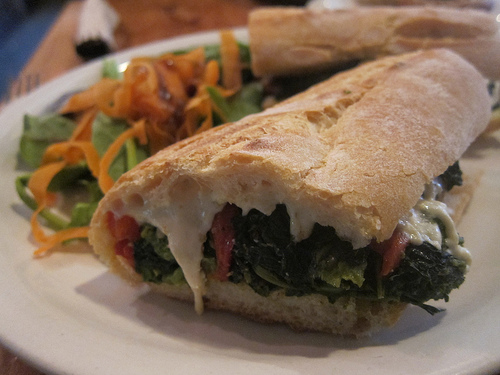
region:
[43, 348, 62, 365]
edge of a plate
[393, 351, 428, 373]
side of a plate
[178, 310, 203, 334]
inside of a plate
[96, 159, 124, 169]
section of vegetables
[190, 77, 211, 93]
part of orange vegetable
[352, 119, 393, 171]
section of a bread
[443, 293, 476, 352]
a white plate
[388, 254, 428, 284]
part of green vegetable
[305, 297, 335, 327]
bottom of a hot dog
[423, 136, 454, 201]
inside of a hot dog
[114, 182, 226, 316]
white sauce on the sandwich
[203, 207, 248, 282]
a piece of red tomato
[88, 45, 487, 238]
a piece of bread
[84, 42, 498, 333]
half of a sandwich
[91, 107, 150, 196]
a piece of cheese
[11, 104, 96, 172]
a leaf of spinach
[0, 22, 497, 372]
a round white plate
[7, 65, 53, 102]
the tines of a fork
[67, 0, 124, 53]
a white napkin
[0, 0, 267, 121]
a brown wooden table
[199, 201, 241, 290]
a red slice of tomato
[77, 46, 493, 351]
a half of a sandwich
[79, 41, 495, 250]
a slice of bread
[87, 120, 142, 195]
a slice of cheese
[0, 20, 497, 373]
a white plate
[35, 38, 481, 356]
A sandwich on a plate.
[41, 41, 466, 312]
A salad next to the sandwich.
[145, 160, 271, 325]
Cheese melting in a sandwich.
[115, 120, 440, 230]
The top of the sandwich.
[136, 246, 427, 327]
The bottom of the sandwich.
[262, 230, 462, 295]
The greens in the sandwich.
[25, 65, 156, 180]
Slivers of carrots on the salad.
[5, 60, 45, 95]
The tines of the fork.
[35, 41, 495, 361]
The food is on a white plate.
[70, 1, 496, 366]
Two sandwiches on the plate.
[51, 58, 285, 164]
Green salad with carrots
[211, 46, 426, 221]
Bread on a sandwich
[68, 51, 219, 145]
Orange carrots on a salad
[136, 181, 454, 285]
Green broccoli in a sandwich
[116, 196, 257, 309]
White sauce on a sandwich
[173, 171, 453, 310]
Red tomatoes on a sandwich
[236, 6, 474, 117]
Bread on a plate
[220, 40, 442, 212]
Brown bread with sauce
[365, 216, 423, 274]
Red pepper on a sandwich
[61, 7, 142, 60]
Silver spoon by a plate